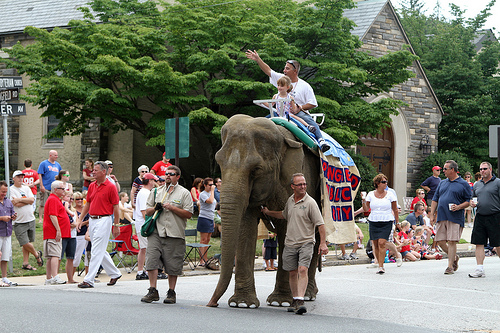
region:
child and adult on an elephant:
[215, 45, 340, 160]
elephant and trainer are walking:
[209, 113, 332, 318]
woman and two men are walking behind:
[356, 156, 497, 278]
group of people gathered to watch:
[1, 158, 191, 306]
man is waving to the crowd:
[243, 45, 313, 76]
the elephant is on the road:
[208, 116, 283, 316]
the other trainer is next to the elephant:
[136, 162, 201, 309]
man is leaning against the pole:
[6, 62, 37, 276]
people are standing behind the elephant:
[190, 112, 342, 317]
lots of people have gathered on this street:
[0, 146, 499, 279]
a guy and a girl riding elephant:
[207, 43, 364, 318]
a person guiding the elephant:
[258, 168, 330, 315]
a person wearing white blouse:
[358, 172, 400, 277]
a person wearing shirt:
[358, 171, 400, 277]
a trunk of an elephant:
[202, 178, 254, 310]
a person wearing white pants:
[73, 158, 125, 288]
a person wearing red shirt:
[73, 157, 125, 289]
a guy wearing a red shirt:
[39, 191, 72, 240]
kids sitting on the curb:
[388, 218, 438, 260]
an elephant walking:
[204, 110, 364, 319]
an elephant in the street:
[205, 113, 327, 309]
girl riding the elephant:
[261, 76, 298, 123]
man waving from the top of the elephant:
[243, 45, 328, 150]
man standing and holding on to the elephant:
[262, 171, 329, 313]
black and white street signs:
[0, 77, 24, 186]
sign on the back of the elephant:
[312, 130, 360, 245]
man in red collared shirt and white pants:
[78, 160, 120, 287]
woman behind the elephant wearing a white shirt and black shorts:
[360, 173, 398, 274]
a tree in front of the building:
[5, 1, 420, 193]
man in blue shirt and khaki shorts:
[430, 160, 469, 273]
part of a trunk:
[207, 195, 257, 290]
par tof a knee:
[290, 252, 315, 279]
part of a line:
[365, 287, 380, 314]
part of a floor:
[373, 297, 393, 328]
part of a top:
[286, 228, 301, 256]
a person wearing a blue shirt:
[431, 160, 459, 277]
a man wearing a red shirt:
[82, 163, 119, 288]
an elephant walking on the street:
[210, 91, 322, 309]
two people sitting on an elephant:
[248, 52, 334, 154]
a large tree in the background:
[21, 9, 424, 139]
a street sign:
[1, 76, 28, 175]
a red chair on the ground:
[117, 228, 144, 268]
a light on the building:
[417, 133, 436, 153]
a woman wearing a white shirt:
[365, 178, 394, 270]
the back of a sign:
[168, 118, 196, 159]